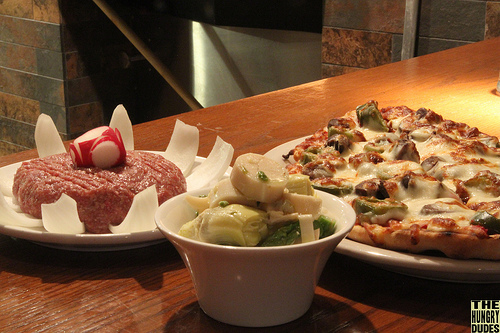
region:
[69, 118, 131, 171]
radish used as a garnish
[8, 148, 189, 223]
patty of ground beef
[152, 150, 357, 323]
artichoke salad in a white bowl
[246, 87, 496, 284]
pizza on a white plate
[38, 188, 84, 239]
piece of onion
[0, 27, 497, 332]
wooden table with food on it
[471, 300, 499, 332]
water mark of "The Hungry Dudes"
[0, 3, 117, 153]
decorative marble brick walls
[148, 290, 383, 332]
bowl casts a shadow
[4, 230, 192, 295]
shadow of the plate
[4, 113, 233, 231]
food is on a plate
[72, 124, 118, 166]
radishes are on top of meat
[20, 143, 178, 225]
the meat is on the plate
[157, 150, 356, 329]
the dish is made of ceramic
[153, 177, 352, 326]
the dish is white in color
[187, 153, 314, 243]
dumplings are in the dish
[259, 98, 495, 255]
pizza is on the dish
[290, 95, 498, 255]
the pizza has a crust all around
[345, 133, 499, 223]
the cheese is white in color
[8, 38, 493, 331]
the table is made of wood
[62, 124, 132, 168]
A grouping of sliced radish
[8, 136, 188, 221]
A raw hamburger patty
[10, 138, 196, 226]
A raw meat patty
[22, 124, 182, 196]
Sliced radish on top of ray ground meat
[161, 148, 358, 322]
A cup of cooked vegetables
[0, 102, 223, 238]
A raw ground beef patty, sliced radishes, and raw onion petals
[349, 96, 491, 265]
A small vegetable pizza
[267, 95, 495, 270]
A small vegetable pizza on a plate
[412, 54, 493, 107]
Varnished golden oak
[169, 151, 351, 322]
Mixed green vegetables in a single serve dish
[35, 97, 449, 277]
food is on the table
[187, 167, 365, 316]
artichoke salad is in the cup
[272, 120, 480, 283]
a pizza is on the plate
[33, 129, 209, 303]
a dessert is on the table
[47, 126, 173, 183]
a peppermint is on the dessert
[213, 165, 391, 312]
an artichoke is in the bowl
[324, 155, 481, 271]
mushroom is on the pizza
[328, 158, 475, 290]
cheese is on the pizza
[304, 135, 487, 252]
peppers are on the pizza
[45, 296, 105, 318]
the table is made of wood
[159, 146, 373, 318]
a plate of salad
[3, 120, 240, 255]
a plate of food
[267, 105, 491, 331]
a plate of icecream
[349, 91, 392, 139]
this is topping on the pizza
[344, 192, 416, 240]
this is topping on the pizza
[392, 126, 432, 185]
this is topping on the pizza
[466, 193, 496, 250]
this is topping on the pizza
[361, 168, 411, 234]
this is topping on the pizza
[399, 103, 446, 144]
this is topping on the pizza